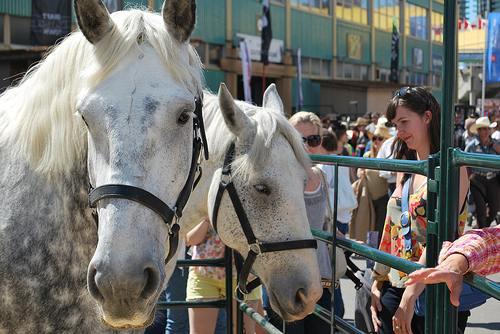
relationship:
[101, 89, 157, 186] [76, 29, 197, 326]
dots on face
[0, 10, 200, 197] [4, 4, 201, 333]
hair on horse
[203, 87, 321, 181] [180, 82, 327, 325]
hair on horse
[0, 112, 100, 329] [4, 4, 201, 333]
pattern on horse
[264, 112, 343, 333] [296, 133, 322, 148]
woman wearing sunglasses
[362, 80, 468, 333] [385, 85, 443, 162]
woman has hair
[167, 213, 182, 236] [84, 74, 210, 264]
ring on bridle strap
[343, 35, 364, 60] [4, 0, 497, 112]
sign on building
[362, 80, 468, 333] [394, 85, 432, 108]
woman with sunglasses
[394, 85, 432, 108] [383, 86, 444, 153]
sunglasses on head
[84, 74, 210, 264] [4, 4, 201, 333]
bridle strap on horse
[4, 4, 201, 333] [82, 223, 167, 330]
horse has nose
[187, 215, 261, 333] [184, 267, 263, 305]
girl wearing shorts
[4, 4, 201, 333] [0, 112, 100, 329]
horse has spots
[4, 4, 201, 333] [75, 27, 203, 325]
horse has head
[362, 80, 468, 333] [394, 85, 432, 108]
woman has sunglasses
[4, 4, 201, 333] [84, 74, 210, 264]
horse has bridle strap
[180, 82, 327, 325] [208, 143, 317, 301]
horse has bridle strap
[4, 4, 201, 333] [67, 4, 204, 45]
horse has ears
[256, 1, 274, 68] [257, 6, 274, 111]
flag on pole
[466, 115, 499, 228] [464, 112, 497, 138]
man wearing hat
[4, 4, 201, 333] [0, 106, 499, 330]
horse in pen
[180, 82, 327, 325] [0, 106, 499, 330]
horse in pen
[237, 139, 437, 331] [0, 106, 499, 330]
gate of pen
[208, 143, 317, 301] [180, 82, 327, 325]
bridle strap on horse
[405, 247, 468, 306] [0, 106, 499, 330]
hand in pen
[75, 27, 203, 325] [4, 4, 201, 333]
head of horse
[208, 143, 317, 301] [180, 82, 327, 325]
head of horse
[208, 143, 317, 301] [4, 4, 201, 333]
head of horse